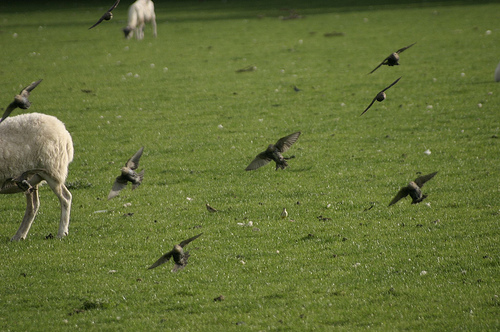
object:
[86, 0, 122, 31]
bird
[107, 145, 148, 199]
bird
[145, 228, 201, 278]
bird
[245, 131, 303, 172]
bird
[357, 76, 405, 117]
bird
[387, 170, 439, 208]
bird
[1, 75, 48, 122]
bird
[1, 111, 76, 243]
sheep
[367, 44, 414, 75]
bird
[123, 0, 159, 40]
animal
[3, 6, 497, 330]
ground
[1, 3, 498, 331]
grass